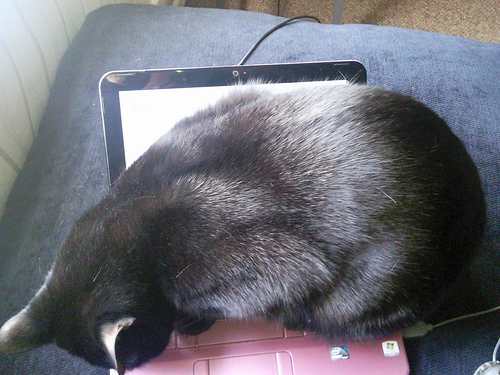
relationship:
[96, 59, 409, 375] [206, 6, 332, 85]
laptop has power supply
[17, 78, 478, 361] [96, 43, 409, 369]
cat laying on laptop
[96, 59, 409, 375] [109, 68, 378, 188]
laptop has monitor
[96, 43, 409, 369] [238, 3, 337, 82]
laptop has power cord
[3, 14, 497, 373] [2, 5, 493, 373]
pillow on couch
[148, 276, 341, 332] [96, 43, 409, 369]
keyboard on laptop